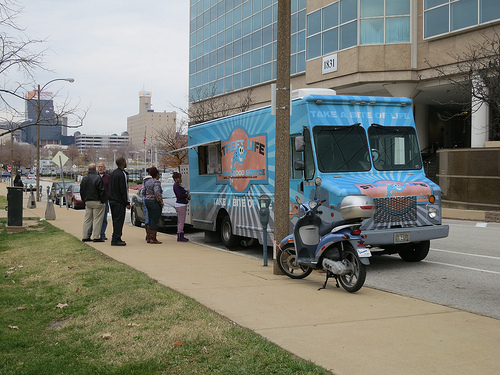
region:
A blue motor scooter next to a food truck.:
[272, 191, 378, 291]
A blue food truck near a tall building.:
[164, 85, 449, 270]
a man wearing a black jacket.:
[97, 153, 132, 250]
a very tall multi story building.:
[123, 81, 180, 163]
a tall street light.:
[31, 73, 74, 206]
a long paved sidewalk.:
[0, 183, 498, 372]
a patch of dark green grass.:
[0, 196, 332, 371]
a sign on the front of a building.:
[316, 48, 341, 75]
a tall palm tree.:
[268, 0, 296, 277]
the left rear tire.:
[208, 213, 243, 248]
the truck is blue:
[138, 77, 453, 282]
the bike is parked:
[278, 174, 393, 330]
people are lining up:
[58, 141, 227, 259]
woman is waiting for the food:
[160, 155, 211, 272]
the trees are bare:
[145, 90, 251, 188]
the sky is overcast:
[55, 25, 202, 120]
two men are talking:
[64, 148, 109, 228]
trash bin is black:
[1, 175, 41, 235]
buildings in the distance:
[13, 87, 189, 174]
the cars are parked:
[28, 163, 198, 241]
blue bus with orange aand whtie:
[151, 91, 423, 276]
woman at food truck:
[159, 153, 219, 244]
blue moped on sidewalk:
[288, 178, 378, 291]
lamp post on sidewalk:
[8, 58, 91, 228]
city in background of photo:
[10, 69, 182, 170]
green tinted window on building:
[175, 3, 499, 71]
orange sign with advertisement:
[198, 121, 294, 221]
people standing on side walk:
[41, 130, 193, 267]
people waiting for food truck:
[37, 149, 199, 240]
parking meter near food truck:
[250, 185, 277, 270]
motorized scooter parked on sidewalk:
[276, 192, 378, 293]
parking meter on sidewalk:
[257, 193, 272, 265]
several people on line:
[75, 153, 196, 245]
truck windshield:
[365, 121, 422, 179]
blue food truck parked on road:
[173, 91, 450, 266]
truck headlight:
[426, 206, 437, 220]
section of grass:
[16, 269, 136, 364]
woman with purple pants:
[166, 167, 190, 247]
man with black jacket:
[96, 153, 133, 244]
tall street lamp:
[32, 70, 77, 204]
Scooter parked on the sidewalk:
[275, 195, 374, 292]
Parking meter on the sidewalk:
[257, 192, 270, 266]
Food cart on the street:
[166, 93, 448, 265]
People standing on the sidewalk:
[80, 155, 190, 244]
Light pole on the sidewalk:
[36, 82, 40, 200]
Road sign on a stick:
[50, 149, 70, 210]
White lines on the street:
[422, 246, 498, 273]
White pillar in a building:
[468, 75, 488, 146]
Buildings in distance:
[4, 82, 185, 164]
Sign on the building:
[320, 54, 337, 73]